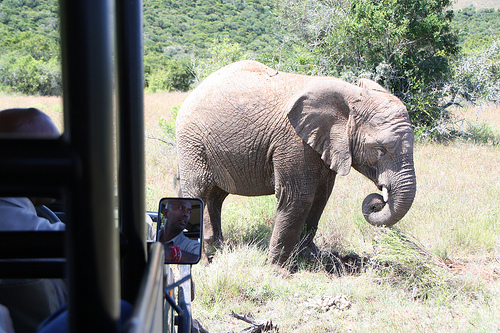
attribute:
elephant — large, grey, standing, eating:
[172, 59, 417, 270]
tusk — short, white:
[381, 186, 390, 202]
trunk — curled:
[362, 174, 420, 229]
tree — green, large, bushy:
[320, 0, 451, 137]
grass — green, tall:
[0, 90, 499, 332]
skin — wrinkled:
[178, 60, 327, 259]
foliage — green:
[3, 1, 498, 110]